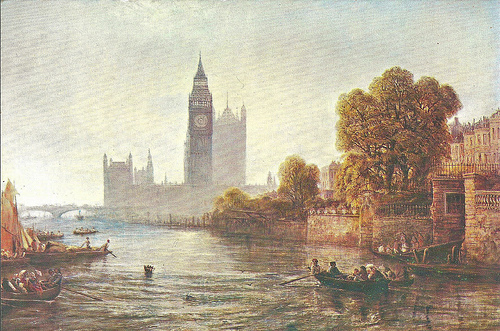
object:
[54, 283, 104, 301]
oar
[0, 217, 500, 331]
water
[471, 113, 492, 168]
housees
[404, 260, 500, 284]
ground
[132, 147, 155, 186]
buildings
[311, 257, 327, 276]
man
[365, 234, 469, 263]
boat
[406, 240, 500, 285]
dock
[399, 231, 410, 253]
people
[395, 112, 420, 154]
leaves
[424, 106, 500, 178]
buildings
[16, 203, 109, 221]
bridge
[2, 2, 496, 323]
painting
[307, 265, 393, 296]
rowboat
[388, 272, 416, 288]
rowboat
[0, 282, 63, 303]
rowboat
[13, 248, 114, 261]
rowboat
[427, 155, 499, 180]
fencing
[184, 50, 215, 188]
clock tower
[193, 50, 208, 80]
spires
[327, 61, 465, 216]
trees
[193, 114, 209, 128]
clock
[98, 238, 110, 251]
people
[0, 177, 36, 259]
sail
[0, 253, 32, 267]
boat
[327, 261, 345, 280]
people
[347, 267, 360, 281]
people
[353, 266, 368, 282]
people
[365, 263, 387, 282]
people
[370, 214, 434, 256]
walls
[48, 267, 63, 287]
people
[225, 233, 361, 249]
waters edge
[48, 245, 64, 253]
goods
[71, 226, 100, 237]
boat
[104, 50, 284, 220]
city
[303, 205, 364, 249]
wall